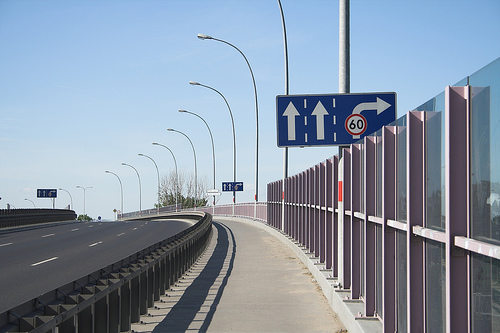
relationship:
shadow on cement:
[193, 217, 239, 329] [179, 202, 336, 329]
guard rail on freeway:
[30, 200, 200, 324] [0, 221, 203, 331]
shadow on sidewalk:
[193, 217, 239, 329] [134, 218, 345, 330]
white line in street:
[113, 227, 127, 238] [7, 199, 169, 320]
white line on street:
[89, 238, 104, 248] [0, 220, 198, 309]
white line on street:
[113, 227, 127, 238] [0, 220, 198, 309]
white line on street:
[28, 254, 56, 267] [0, 220, 198, 309]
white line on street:
[41, 231, 54, 239] [0, 220, 198, 309]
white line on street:
[70, 226, 80, 232] [0, 220, 198, 309]